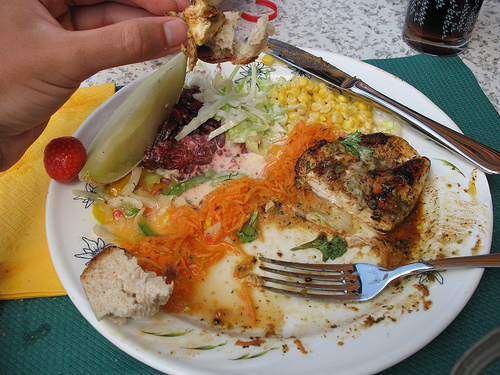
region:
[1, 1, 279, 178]
Hand holding food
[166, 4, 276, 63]
The person is holding bread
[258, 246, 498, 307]
Fork resting on the plate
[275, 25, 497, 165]
Knife resting on the plate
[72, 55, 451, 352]
Plate with food all over it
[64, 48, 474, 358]
Much of the food has been eaten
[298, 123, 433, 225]
A piece of chicken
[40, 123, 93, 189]
A red strawberry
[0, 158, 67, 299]
A yellow napkin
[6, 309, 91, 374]
A green place mat under the plate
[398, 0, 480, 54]
a glass on the table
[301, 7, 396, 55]
white and grey table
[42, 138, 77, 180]
a strawberry on the plate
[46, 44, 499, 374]
a white plate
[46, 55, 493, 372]
food on a white plate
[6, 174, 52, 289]
a yellow napkin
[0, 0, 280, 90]
a hand holding food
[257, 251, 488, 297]
a fork on the plate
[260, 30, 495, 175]
a silver knife on the plate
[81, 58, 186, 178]
a pickle on the plate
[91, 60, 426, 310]
food is on the plate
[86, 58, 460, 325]
plate has food on it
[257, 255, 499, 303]
fork is on the plate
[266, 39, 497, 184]
knife is on the plate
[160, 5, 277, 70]
person is holding food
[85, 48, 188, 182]
pickle is on the plate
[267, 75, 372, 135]
corn is on the plate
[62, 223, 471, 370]
plate is white in color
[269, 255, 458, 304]
fork is silver in color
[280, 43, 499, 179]
knife is silver and shiny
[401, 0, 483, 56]
Clear glass filled with dark beverage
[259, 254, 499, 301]
Shiny metal fork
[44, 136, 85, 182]
Round red berry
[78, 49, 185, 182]
Slice of pale green melon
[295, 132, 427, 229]
Half of a seasoned chicken breast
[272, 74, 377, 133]
Small portion of cooked corn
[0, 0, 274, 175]
Hand holding a piece of bread and chicken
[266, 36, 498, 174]
Shiny metal knife resting on white plate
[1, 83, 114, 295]
Yellow napkin resting beneath white plate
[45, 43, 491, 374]
Large plate of food resting on green place mat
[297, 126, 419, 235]
chicken on a plate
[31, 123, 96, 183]
strawberries on a plate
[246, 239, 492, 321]
fork on a plate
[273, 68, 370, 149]
corn on a plate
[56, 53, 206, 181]
pickle on a plate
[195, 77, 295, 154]
cabbage on a plate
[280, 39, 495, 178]
knife on a plate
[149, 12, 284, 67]
person holding a piece of bread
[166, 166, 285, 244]
carrots on a plate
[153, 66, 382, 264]
food on a plate